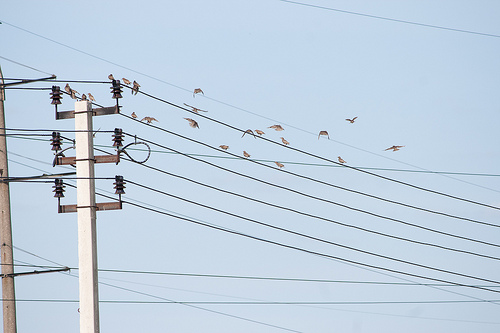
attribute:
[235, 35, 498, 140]
skies — blue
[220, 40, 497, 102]
sky — blue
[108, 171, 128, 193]
insulator — single, power, line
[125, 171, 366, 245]
clouds — white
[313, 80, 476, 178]
clouds — white 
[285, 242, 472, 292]
cloud — white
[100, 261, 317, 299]
cloud — white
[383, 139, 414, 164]
bird — flying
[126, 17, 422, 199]
clouds — white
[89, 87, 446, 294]
clouds — white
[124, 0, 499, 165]
sky — blue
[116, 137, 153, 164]
wire — overlaped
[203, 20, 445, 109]
sky — blue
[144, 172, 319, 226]
clouds — white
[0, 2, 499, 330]
sky — blue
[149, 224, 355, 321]
clouds — white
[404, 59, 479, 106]
sky — blue, white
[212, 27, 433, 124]
sky — blue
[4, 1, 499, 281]
sky — blue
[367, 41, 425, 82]
clouds — white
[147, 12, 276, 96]
sky — blue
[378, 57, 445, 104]
sky — blue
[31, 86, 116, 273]
pole — white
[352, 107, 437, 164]
clouds — white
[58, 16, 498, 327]
clouds — white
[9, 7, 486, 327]
clouds — white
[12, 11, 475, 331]
sky — blue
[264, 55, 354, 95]
clouds — white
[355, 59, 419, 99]
clouds — white